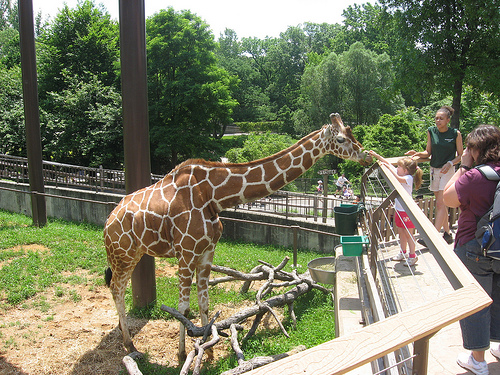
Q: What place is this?
A: It is a zoo.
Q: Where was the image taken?
A: It was taken at the zoo.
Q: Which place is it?
A: It is a zoo.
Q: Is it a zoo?
A: Yes, it is a zoo.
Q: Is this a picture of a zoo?
A: Yes, it is showing a zoo.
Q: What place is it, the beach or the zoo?
A: It is the zoo.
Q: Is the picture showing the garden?
A: No, the picture is showing the zoo.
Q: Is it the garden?
A: No, it is the zoo.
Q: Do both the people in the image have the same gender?
A: Yes, all the people are female.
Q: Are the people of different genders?
A: No, all the people are female.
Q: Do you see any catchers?
A: No, there are no catchers.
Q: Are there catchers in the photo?
A: No, there are no catchers.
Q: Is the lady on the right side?
A: Yes, the lady is on the right of the image.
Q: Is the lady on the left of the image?
A: No, the lady is on the right of the image.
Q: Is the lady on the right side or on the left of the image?
A: The lady is on the right of the image.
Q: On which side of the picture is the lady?
A: The lady is on the right of the image.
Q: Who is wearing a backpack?
A: The lady is wearing a backpack.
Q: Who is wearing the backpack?
A: The lady is wearing a backpack.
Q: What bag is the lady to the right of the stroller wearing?
A: The lady is wearing a backpack.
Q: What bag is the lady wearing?
A: The lady is wearing a backpack.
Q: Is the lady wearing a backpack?
A: Yes, the lady is wearing a backpack.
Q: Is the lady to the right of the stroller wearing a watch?
A: No, the lady is wearing a backpack.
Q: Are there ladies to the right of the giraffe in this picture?
A: Yes, there is a lady to the right of the giraffe.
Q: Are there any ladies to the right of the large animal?
A: Yes, there is a lady to the right of the giraffe.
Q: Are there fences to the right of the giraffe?
A: No, there is a lady to the right of the giraffe.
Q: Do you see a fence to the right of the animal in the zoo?
A: No, there is a lady to the right of the giraffe.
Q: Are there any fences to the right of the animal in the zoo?
A: No, there is a lady to the right of the giraffe.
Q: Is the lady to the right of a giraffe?
A: Yes, the lady is to the right of a giraffe.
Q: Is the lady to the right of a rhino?
A: No, the lady is to the right of a giraffe.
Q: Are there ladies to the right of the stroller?
A: Yes, there is a lady to the right of the stroller.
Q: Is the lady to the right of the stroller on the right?
A: Yes, the lady is to the right of the stroller.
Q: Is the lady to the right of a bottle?
A: No, the lady is to the right of the stroller.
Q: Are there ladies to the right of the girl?
A: Yes, there is a lady to the right of the girl.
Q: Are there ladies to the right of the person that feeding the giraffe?
A: Yes, there is a lady to the right of the girl.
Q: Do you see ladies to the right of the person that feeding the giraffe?
A: Yes, there is a lady to the right of the girl.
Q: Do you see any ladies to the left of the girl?
A: No, the lady is to the right of the girl.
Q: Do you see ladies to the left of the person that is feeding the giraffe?
A: No, the lady is to the right of the girl.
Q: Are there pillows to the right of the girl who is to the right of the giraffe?
A: No, there is a lady to the right of the girl.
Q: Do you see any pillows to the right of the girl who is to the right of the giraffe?
A: No, there is a lady to the right of the girl.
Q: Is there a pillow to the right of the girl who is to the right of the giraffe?
A: No, there is a lady to the right of the girl.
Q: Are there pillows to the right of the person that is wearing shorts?
A: No, there is a lady to the right of the girl.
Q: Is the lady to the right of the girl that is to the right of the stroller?
A: Yes, the lady is to the right of the girl.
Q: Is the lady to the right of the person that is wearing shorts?
A: Yes, the lady is to the right of the girl.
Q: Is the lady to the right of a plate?
A: No, the lady is to the right of the girl.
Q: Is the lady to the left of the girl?
A: No, the lady is to the right of the girl.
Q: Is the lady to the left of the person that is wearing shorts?
A: No, the lady is to the right of the girl.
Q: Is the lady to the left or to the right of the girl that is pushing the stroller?
A: The lady is to the right of the girl.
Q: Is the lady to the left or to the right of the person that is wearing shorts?
A: The lady is to the right of the girl.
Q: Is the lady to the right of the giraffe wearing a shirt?
A: Yes, the lady is wearing a shirt.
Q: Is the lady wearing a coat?
A: No, the lady is wearing a shirt.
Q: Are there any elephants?
A: No, there are no elephants.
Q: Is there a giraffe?
A: Yes, there is a giraffe.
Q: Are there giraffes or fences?
A: Yes, there is a giraffe.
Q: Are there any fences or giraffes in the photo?
A: Yes, there is a giraffe.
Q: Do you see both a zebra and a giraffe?
A: No, there is a giraffe but no zebras.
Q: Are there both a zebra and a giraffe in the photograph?
A: No, there is a giraffe but no zebras.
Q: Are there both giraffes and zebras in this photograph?
A: No, there is a giraffe but no zebras.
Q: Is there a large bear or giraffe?
A: Yes, there is a large giraffe.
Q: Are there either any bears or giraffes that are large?
A: Yes, the giraffe is large.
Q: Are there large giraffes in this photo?
A: Yes, there is a large giraffe.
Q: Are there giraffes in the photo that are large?
A: Yes, there is a giraffe that is large.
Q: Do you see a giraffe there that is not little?
A: Yes, there is a large giraffe.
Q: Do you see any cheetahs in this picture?
A: No, there are no cheetahs.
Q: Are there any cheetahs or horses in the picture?
A: No, there are no cheetahs or horses.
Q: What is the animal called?
A: The animal is a giraffe.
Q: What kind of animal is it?
A: The animal is a giraffe.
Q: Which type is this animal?
A: This is a giraffe.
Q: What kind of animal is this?
A: This is a giraffe.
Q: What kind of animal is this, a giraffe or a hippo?
A: This is a giraffe.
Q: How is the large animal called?
A: The animal is a giraffe.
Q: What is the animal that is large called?
A: The animal is a giraffe.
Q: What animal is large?
A: The animal is a giraffe.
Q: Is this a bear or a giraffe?
A: This is a giraffe.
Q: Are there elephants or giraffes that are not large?
A: No, there is a giraffe but it is large.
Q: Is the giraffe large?
A: Yes, the giraffe is large.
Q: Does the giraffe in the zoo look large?
A: Yes, the giraffe is large.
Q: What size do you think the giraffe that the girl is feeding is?
A: The giraffe is large.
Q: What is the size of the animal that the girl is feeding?
A: The giraffe is large.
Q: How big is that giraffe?
A: The giraffe is large.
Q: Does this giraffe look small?
A: No, the giraffe is large.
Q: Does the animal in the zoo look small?
A: No, the giraffe is large.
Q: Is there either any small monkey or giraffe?
A: No, there is a giraffe but it is large.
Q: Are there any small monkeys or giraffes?
A: No, there is a giraffe but it is large.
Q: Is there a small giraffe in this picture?
A: No, there is a giraffe but it is large.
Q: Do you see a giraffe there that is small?
A: No, there is a giraffe but it is large.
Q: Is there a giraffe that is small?
A: No, there is a giraffe but it is large.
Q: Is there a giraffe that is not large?
A: No, there is a giraffe but it is large.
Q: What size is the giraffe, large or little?
A: The giraffe is large.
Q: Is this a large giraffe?
A: Yes, this is a large giraffe.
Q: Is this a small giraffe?
A: No, this is a large giraffe.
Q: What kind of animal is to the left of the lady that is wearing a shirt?
A: The animal is a giraffe.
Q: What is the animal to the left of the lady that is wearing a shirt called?
A: The animal is a giraffe.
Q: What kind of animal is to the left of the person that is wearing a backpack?
A: The animal is a giraffe.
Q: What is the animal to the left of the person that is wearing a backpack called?
A: The animal is a giraffe.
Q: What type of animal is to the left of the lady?
A: The animal is a giraffe.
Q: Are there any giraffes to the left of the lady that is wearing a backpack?
A: Yes, there is a giraffe to the left of the lady.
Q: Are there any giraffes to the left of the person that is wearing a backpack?
A: Yes, there is a giraffe to the left of the lady.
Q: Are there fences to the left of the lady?
A: No, there is a giraffe to the left of the lady.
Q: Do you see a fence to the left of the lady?
A: No, there is a giraffe to the left of the lady.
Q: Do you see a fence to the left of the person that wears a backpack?
A: No, there is a giraffe to the left of the lady.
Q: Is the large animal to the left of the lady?
A: Yes, the giraffe is to the left of the lady.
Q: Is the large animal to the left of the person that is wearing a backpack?
A: Yes, the giraffe is to the left of the lady.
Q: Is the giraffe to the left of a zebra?
A: No, the giraffe is to the left of the lady.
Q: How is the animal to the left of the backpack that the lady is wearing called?
A: The animal is a giraffe.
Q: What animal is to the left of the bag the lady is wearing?
A: The animal is a giraffe.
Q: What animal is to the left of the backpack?
A: The animal is a giraffe.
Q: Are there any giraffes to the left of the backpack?
A: Yes, there is a giraffe to the left of the backpack.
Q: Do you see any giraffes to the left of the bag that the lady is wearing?
A: Yes, there is a giraffe to the left of the backpack.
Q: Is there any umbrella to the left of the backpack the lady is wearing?
A: No, there is a giraffe to the left of the backpack.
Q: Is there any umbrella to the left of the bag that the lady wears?
A: No, there is a giraffe to the left of the backpack.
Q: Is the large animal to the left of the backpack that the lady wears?
A: Yes, the giraffe is to the left of the backpack.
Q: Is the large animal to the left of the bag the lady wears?
A: Yes, the giraffe is to the left of the backpack.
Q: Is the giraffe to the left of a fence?
A: No, the giraffe is to the left of the backpack.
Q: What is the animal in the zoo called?
A: The animal is a giraffe.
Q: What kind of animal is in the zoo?
A: The animal is a giraffe.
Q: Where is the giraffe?
A: The giraffe is in the zoo.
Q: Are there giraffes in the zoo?
A: Yes, there is a giraffe in the zoo.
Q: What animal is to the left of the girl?
A: The animal is a giraffe.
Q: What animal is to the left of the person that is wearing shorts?
A: The animal is a giraffe.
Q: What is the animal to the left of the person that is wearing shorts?
A: The animal is a giraffe.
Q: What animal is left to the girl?
A: The animal is a giraffe.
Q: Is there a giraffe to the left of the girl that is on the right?
A: Yes, there is a giraffe to the left of the girl.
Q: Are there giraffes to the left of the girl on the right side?
A: Yes, there is a giraffe to the left of the girl.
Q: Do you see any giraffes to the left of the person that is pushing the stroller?
A: Yes, there is a giraffe to the left of the girl.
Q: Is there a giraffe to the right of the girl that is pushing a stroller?
A: No, the giraffe is to the left of the girl.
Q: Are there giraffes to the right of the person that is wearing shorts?
A: No, the giraffe is to the left of the girl.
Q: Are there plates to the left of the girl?
A: No, there is a giraffe to the left of the girl.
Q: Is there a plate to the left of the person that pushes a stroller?
A: No, there is a giraffe to the left of the girl.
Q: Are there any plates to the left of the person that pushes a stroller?
A: No, there is a giraffe to the left of the girl.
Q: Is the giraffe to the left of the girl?
A: Yes, the giraffe is to the left of the girl.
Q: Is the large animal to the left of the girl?
A: Yes, the giraffe is to the left of the girl.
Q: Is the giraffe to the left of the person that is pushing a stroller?
A: Yes, the giraffe is to the left of the girl.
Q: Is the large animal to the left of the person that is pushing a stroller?
A: Yes, the giraffe is to the left of the girl.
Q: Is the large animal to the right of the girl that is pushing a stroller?
A: No, the giraffe is to the left of the girl.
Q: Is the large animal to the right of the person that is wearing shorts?
A: No, the giraffe is to the left of the girl.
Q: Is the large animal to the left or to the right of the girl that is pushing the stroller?
A: The giraffe is to the left of the girl.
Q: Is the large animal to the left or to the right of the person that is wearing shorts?
A: The giraffe is to the left of the girl.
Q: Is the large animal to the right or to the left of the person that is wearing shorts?
A: The giraffe is to the left of the girl.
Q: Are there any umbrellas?
A: No, there are no umbrellas.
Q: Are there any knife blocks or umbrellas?
A: No, there are no umbrellas or knife blocks.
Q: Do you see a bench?
A: No, there are no benches.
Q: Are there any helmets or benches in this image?
A: No, there are no benches or helmets.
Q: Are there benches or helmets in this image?
A: No, there are no benches or helmets.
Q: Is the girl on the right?
A: Yes, the girl is on the right of the image.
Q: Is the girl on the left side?
A: No, the girl is on the right of the image.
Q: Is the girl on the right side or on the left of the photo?
A: The girl is on the right of the image.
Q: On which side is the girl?
A: The girl is on the right of the image.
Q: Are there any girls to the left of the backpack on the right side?
A: Yes, there is a girl to the left of the backpack.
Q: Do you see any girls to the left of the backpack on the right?
A: Yes, there is a girl to the left of the backpack.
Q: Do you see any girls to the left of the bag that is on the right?
A: Yes, there is a girl to the left of the backpack.